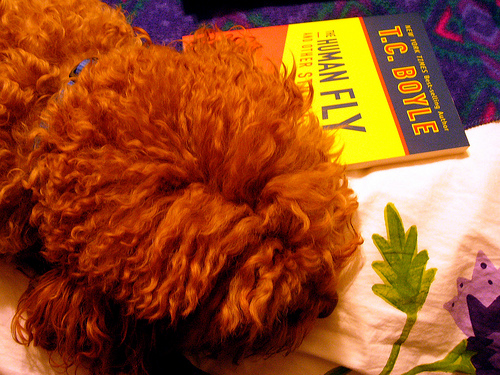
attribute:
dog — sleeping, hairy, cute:
[0, 2, 364, 367]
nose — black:
[319, 291, 340, 316]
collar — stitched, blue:
[70, 55, 95, 78]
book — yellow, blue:
[183, 16, 470, 175]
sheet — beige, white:
[1, 120, 498, 373]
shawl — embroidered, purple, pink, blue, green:
[103, 0, 499, 131]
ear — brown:
[14, 269, 115, 372]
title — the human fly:
[317, 32, 365, 134]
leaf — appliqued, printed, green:
[372, 202, 438, 373]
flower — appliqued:
[445, 252, 499, 336]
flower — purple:
[444, 250, 498, 373]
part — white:
[2, 261, 37, 374]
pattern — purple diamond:
[204, 2, 499, 130]